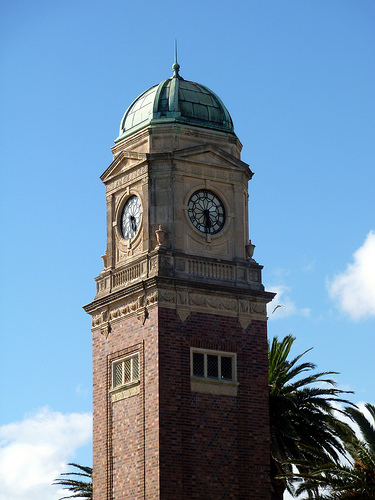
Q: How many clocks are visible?
A: Two.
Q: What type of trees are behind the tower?
A: Palm.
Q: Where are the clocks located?
A: The Tower.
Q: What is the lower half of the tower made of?
A: Bricks.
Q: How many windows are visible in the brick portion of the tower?
A: Six.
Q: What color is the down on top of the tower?
A: Green.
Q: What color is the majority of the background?
A: Blue.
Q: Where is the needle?
A: Top of tower.